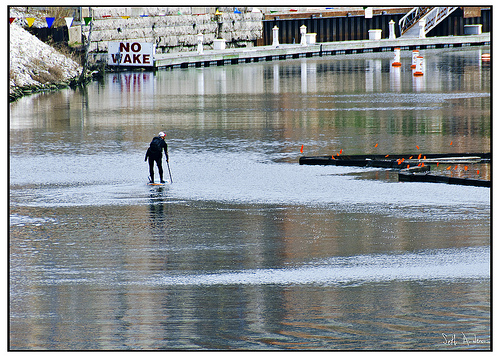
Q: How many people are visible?
A: One.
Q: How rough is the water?
A: Flat and calm.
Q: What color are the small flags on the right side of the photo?
A: Orange.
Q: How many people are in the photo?
A: One.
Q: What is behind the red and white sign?
A: A stone wall.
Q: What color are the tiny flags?
A: Orange.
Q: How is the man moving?
A: With a paddle.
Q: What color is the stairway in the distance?
A: White.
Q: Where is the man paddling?
A: In water.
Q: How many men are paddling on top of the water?
A: One.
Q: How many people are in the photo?
A: One.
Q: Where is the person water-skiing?
A: On a body of water.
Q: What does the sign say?
A: No wake.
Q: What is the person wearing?
A: A wetsuit.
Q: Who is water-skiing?
A: A person.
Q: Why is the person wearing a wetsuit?
A: Because they are water-skiing.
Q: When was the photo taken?
A: During the day.